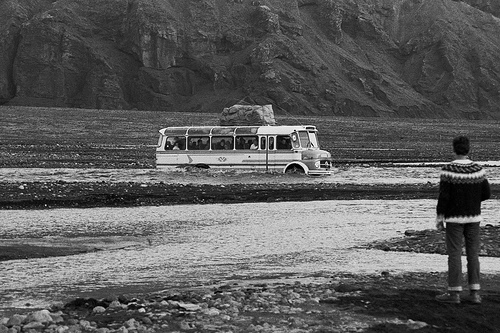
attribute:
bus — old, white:
[155, 118, 333, 179]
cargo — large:
[218, 98, 277, 126]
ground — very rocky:
[1, 103, 500, 331]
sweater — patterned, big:
[436, 159, 492, 225]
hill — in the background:
[2, 2, 499, 122]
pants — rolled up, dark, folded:
[444, 217, 483, 294]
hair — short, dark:
[451, 131, 472, 157]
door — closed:
[259, 132, 276, 170]